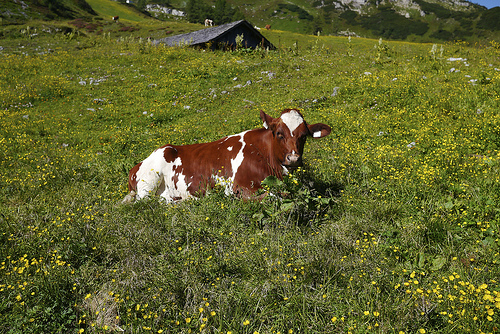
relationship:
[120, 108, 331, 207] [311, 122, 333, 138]
cow left ear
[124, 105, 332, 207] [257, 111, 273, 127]
cow right ear